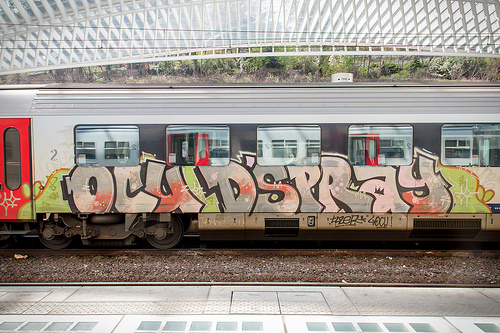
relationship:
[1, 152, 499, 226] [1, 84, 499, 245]
graffiti on train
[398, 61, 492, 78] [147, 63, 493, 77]
bushes are behind opening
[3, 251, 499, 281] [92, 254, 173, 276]
ground has gravel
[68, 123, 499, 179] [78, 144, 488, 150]
five windows are next to each other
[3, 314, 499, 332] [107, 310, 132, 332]
fifteen squares separated by lines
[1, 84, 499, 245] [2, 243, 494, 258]
train on train track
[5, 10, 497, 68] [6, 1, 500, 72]
square lines are in ceiling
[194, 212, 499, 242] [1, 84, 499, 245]
bracket under train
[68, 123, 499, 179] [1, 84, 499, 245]
five windows of train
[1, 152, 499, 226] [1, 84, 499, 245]
graffiti on side of train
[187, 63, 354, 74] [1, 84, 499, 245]
trees are behind train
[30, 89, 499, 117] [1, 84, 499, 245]
grey lines are on train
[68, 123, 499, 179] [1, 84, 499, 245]
five windows are on side of train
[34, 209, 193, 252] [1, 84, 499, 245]
wheels are on train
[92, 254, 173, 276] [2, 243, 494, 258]
gravel beneath train track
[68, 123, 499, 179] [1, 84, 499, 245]
five windows are on train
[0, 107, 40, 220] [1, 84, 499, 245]
door on train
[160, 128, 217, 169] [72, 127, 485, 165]
open door from other train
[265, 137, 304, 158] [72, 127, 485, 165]
window from other train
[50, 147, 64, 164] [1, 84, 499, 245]
number on train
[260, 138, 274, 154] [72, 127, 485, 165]
number from other train